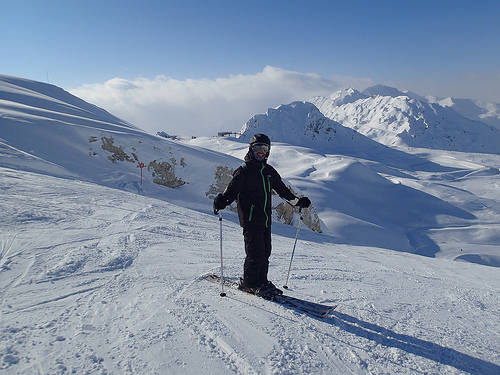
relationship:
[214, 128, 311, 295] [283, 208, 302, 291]
man holding ski pole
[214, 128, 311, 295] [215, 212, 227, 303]
man holding ski pole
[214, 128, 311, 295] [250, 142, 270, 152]
man wearing goggles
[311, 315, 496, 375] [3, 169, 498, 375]
shadow on snow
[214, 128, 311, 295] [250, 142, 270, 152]
man has goggles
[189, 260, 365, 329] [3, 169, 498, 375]
tracks are in snow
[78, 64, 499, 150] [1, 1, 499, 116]
cloud in sky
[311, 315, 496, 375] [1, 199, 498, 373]
shadow on ground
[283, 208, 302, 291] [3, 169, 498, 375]
ski pole on snow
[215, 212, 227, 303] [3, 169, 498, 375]
ski pole on snow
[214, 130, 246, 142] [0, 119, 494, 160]
structure in background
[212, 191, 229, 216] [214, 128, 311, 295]
hand of man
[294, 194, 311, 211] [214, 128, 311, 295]
hand of man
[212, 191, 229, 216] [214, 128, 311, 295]
hand of person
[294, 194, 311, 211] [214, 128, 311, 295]
hand of person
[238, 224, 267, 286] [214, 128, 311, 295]
leg of man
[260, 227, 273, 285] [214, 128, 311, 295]
leg of man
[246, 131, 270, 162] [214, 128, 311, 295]
head of man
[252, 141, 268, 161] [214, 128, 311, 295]
face of man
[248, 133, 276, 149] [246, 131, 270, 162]
protective gear on head